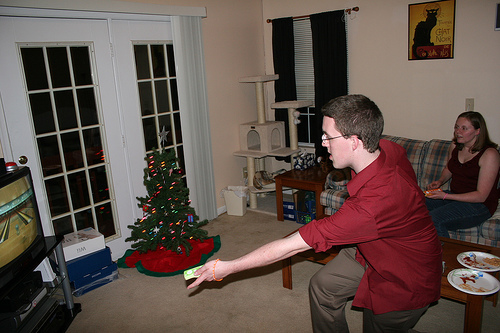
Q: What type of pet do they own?
A: Cat.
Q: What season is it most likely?
A: Winter.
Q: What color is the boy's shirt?
A: Red.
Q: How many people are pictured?
A: 2.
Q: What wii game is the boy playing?
A: Bowling.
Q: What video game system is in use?
A: Wii.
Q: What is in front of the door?
A: Christmas tree.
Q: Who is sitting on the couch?
A: Woman.